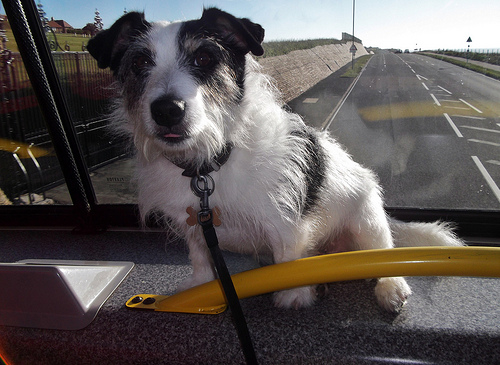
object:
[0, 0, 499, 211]
window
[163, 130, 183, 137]
dog's tongue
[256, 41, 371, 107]
stone wall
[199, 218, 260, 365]
leash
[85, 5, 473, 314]
dog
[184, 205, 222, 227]
dog tag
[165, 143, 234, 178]
collar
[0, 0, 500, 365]
car